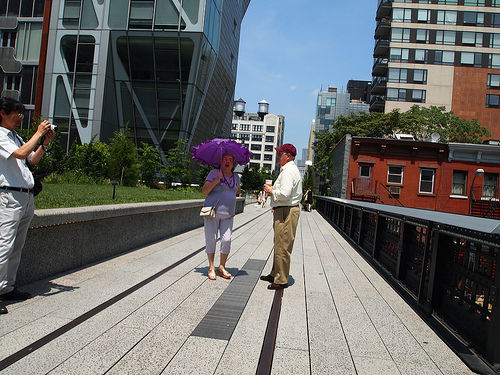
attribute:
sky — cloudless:
[225, 0, 380, 127]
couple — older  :
[191, 135, 308, 300]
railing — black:
[318, 182, 498, 362]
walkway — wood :
[17, 159, 477, 371]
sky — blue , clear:
[251, 23, 329, 80]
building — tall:
[366, 3, 497, 144]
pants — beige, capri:
[197, 209, 242, 265]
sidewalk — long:
[213, 142, 396, 373]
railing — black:
[312, 195, 498, 370]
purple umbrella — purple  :
[187, 135, 252, 171]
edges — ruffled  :
[190, 137, 252, 169]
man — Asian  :
[1, 84, 63, 326]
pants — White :
[269, 203, 300, 285]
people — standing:
[190, 135, 250, 285]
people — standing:
[259, 130, 303, 292]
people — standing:
[0, 93, 55, 315]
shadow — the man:
[25, 270, 75, 304]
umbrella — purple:
[202, 130, 252, 172]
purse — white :
[200, 207, 213, 219]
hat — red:
[267, 140, 300, 160]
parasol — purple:
[186, 133, 259, 186]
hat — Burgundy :
[268, 137, 304, 159]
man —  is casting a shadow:
[264, 132, 308, 291]